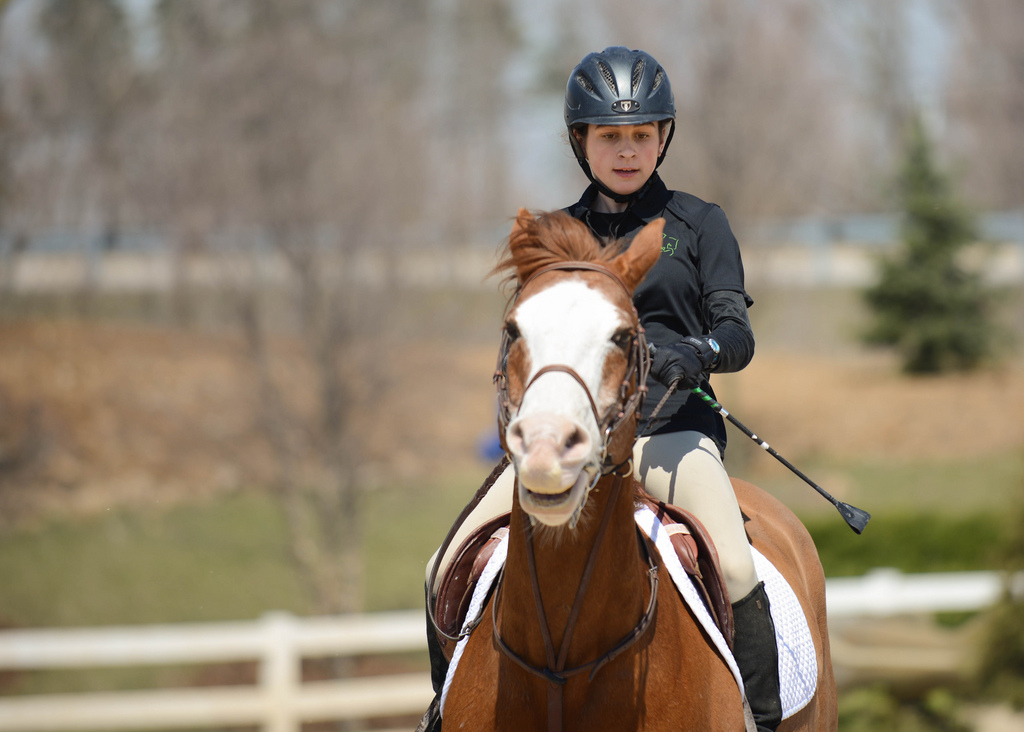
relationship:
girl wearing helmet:
[416, 42, 781, 732] [561, 46, 678, 194]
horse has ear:
[401, 155, 920, 728] [602, 163, 691, 302]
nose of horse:
[501, 411, 582, 463] [427, 206, 842, 727]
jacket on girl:
[528, 169, 756, 463] [512, 42, 778, 693]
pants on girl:
[417, 420, 778, 637] [456, 46, 794, 690]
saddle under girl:
[435, 501, 736, 669] [426, 42, 805, 706]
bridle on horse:
[488, 264, 661, 691] [389, 203, 796, 707]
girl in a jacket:
[416, 42, 781, 732] [484, 175, 757, 472]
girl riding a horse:
[416, 42, 781, 732] [392, 31, 855, 704]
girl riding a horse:
[416, 42, 781, 732] [427, 206, 842, 727]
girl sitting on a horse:
[416, 42, 781, 732] [427, 206, 842, 727]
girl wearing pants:
[416, 42, 781, 732] [476, 404, 768, 729]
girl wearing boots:
[416, 42, 781, 732] [731, 580, 785, 732]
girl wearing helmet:
[392, 54, 807, 724] [504, 54, 706, 158]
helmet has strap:
[551, 48, 688, 137] [551, 126, 683, 198]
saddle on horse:
[398, 499, 744, 674] [389, 203, 796, 707]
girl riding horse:
[416, 42, 781, 732] [389, 203, 796, 707]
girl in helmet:
[416, 42, 781, 732] [564, 46, 677, 126]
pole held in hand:
[692, 386, 872, 535] [651, 336, 716, 396]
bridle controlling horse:
[488, 264, 659, 686] [427, 206, 842, 727]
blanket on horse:
[436, 498, 819, 725] [427, 206, 842, 727]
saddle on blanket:
[435, 501, 736, 669] [436, 498, 819, 725]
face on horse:
[494, 275, 631, 528] [427, 206, 842, 727]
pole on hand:
[687, 394, 871, 539] [637, 320, 711, 396]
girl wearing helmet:
[416, 42, 781, 732] [566, 44, 675, 200]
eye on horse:
[602, 325, 641, 354] [427, 206, 842, 727]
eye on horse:
[499, 316, 523, 351] [427, 206, 842, 727]